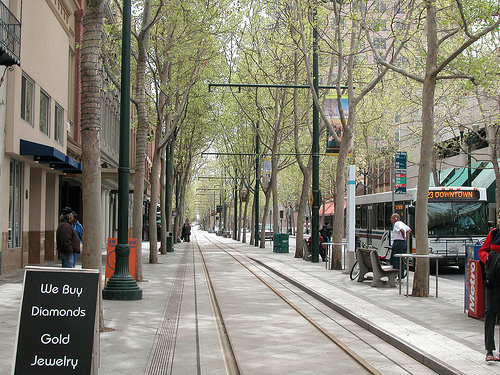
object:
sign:
[10, 264, 99, 374]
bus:
[343, 185, 487, 271]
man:
[389, 212, 410, 283]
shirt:
[390, 219, 411, 241]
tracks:
[191, 226, 466, 374]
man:
[55, 205, 80, 267]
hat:
[61, 204, 73, 213]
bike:
[350, 235, 394, 281]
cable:
[206, 82, 356, 93]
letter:
[39, 281, 54, 293]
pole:
[100, 0, 143, 301]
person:
[476, 209, 499, 365]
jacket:
[478, 249, 500, 287]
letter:
[60, 283, 71, 294]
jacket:
[54, 219, 81, 252]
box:
[468, 259, 487, 319]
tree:
[362, 0, 500, 308]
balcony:
[0, 1, 24, 71]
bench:
[353, 246, 400, 289]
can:
[271, 230, 289, 252]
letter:
[30, 304, 40, 315]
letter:
[40, 332, 53, 345]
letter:
[30, 351, 40, 369]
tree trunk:
[78, 0, 108, 331]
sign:
[105, 237, 139, 279]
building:
[1, 1, 85, 275]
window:
[20, 69, 35, 130]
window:
[375, 200, 383, 230]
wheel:
[348, 259, 362, 281]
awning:
[21, 136, 67, 168]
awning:
[51, 150, 81, 174]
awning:
[469, 156, 499, 205]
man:
[452, 208, 475, 233]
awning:
[63, 162, 84, 175]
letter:
[75, 285, 83, 297]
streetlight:
[210, 208, 215, 220]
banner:
[321, 94, 355, 159]